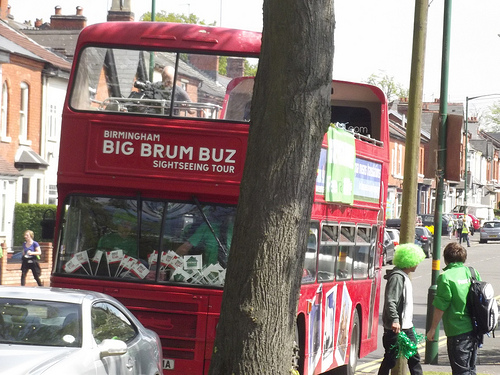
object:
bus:
[49, 22, 392, 374]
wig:
[389, 241, 424, 269]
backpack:
[467, 280, 498, 333]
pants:
[444, 331, 481, 374]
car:
[0, 287, 164, 374]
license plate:
[150, 356, 173, 370]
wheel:
[326, 305, 361, 375]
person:
[423, 242, 483, 375]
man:
[134, 66, 194, 115]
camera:
[133, 78, 147, 93]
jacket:
[430, 263, 482, 338]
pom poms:
[386, 327, 422, 355]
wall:
[0, 53, 41, 161]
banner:
[322, 127, 357, 207]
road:
[0, 240, 497, 373]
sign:
[326, 130, 354, 150]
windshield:
[52, 192, 240, 287]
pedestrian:
[17, 228, 40, 285]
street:
[352, 234, 498, 366]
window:
[172, 47, 262, 121]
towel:
[324, 123, 353, 206]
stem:
[206, 1, 334, 374]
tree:
[205, 1, 334, 374]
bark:
[207, 0, 331, 374]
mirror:
[97, 339, 129, 355]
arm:
[384, 276, 405, 324]